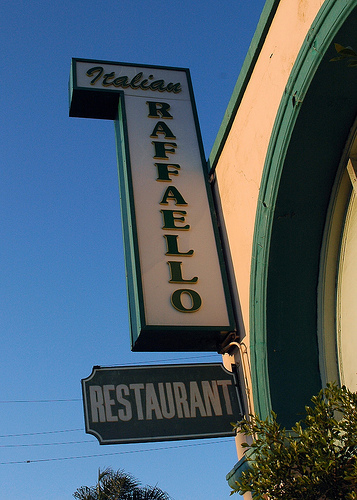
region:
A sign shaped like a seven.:
[63, 49, 245, 354]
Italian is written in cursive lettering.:
[57, 40, 251, 102]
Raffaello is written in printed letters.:
[135, 96, 209, 326]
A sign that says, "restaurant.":
[70, 358, 256, 453]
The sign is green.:
[76, 360, 255, 452]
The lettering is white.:
[70, 363, 258, 447]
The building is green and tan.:
[167, 1, 356, 498]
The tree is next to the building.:
[225, 377, 356, 497]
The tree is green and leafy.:
[227, 373, 356, 498]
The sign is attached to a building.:
[63, 37, 356, 357]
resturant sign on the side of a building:
[77, 360, 254, 446]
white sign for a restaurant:
[54, 51, 247, 352]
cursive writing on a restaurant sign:
[74, 44, 206, 101]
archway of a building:
[211, 28, 329, 407]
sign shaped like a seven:
[68, 42, 263, 362]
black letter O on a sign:
[162, 279, 221, 323]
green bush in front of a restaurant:
[217, 357, 343, 485]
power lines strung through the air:
[11, 361, 68, 489]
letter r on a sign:
[143, 85, 179, 119]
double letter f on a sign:
[151, 130, 185, 189]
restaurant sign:
[25, 313, 235, 449]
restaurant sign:
[58, 353, 255, 490]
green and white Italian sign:
[64, 52, 198, 107]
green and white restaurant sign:
[73, 355, 262, 446]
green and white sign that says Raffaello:
[118, 92, 238, 342]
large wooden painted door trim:
[270, 47, 339, 173]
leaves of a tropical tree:
[77, 463, 185, 498]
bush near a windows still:
[231, 395, 354, 498]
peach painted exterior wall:
[229, 119, 273, 195]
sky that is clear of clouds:
[16, 235, 113, 356]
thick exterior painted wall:
[239, 124, 332, 239]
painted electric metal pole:
[220, 340, 270, 446]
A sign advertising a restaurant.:
[67, 359, 256, 451]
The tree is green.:
[225, 382, 356, 497]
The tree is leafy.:
[224, 377, 356, 496]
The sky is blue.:
[1, 2, 354, 496]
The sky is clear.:
[1, 0, 341, 497]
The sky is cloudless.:
[0, 0, 269, 496]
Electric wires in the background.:
[0, 392, 251, 466]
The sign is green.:
[53, 49, 245, 349]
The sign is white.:
[47, 49, 260, 348]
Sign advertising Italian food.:
[62, 53, 242, 350]